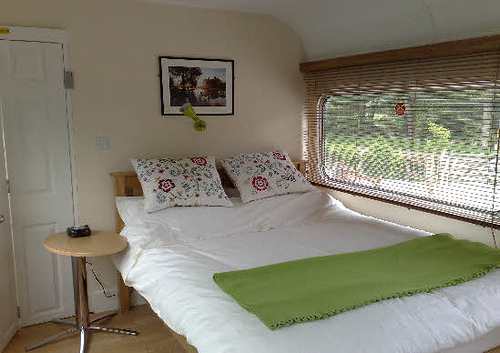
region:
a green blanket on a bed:
[216, 223, 498, 332]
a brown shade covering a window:
[291, 50, 497, 229]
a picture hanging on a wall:
[158, 51, 238, 118]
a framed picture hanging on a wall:
[157, 49, 242, 120]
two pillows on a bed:
[125, 136, 309, 217]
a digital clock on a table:
[60, 219, 96, 243]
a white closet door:
[0, 28, 72, 325]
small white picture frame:
[154, 51, 238, 125]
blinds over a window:
[298, 58, 495, 215]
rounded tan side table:
[40, 223, 130, 350]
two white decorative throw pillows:
[132, 153, 316, 208]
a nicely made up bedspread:
[115, 144, 497, 351]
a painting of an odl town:
[161, 61, 236, 122]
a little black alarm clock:
[61, 218, 96, 240]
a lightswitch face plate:
[91, 133, 109, 155]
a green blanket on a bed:
[214, 228, 498, 334]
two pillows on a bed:
[128, 143, 302, 206]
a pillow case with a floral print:
[226, 142, 310, 204]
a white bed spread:
[140, 216, 477, 338]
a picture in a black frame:
[153, 51, 238, 126]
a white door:
[0, 31, 75, 334]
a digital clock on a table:
[62, 222, 93, 256]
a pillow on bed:
[236, 145, 342, 251]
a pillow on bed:
[164, 138, 226, 226]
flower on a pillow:
[133, 147, 199, 216]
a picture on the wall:
[150, 47, 260, 133]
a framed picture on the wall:
[171, 54, 248, 134]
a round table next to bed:
[60, 192, 160, 343]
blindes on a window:
[267, 17, 495, 240]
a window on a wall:
[315, 59, 494, 211]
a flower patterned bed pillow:
[128, 155, 233, 212]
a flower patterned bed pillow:
[217, 149, 314, 201]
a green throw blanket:
[211, 230, 498, 327]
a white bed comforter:
[111, 190, 498, 351]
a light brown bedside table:
[23, 225, 141, 352]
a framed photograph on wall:
[156, 54, 237, 117]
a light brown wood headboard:
[109, 160, 308, 312]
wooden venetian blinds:
[295, 34, 499, 230]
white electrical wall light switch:
[92, 135, 110, 151]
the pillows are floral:
[131, 145, 345, 229]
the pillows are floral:
[122, 146, 307, 211]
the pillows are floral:
[131, 150, 326, 211]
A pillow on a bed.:
[216, 142, 316, 197]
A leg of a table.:
[89, 323, 141, 338]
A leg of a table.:
[76, 327, 89, 352]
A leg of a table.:
[42, 312, 81, 324]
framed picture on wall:
[145, 28, 267, 142]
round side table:
[15, 215, 145, 348]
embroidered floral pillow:
[115, 133, 230, 223]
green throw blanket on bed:
[199, 205, 498, 347]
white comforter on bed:
[107, 190, 498, 351]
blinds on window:
[303, 27, 497, 244]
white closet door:
[6, 26, 85, 349]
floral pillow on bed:
[215, 138, 322, 203]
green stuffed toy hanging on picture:
[165, 87, 229, 151]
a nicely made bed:
[103, 129, 488, 347]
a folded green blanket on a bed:
[186, 223, 498, 330]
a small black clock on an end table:
[39, 221, 129, 348]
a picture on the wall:
[157, 49, 252, 133]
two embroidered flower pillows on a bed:
[125, 134, 328, 223]